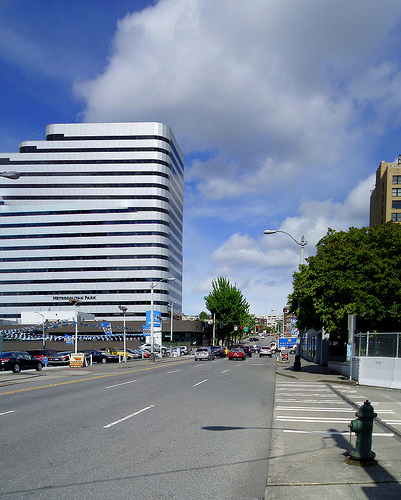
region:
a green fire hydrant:
[339, 394, 395, 463]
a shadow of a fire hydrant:
[362, 460, 399, 497]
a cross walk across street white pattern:
[277, 375, 399, 436]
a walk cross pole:
[342, 317, 352, 379]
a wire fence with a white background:
[356, 332, 400, 385]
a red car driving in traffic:
[225, 346, 248, 364]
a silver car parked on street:
[192, 343, 210, 360]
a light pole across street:
[148, 276, 158, 360]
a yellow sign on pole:
[69, 346, 87, 366]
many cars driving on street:
[192, 320, 285, 376]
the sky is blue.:
[1, 4, 393, 309]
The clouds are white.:
[78, 4, 399, 284]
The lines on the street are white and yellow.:
[0, 355, 244, 442]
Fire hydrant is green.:
[344, 396, 378, 462]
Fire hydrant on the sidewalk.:
[345, 395, 374, 465]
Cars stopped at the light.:
[190, 321, 283, 363]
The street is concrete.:
[0, 345, 289, 496]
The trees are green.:
[276, 218, 399, 329]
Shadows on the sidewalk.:
[194, 410, 400, 495]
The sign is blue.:
[142, 308, 164, 336]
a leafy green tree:
[198, 268, 262, 333]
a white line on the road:
[100, 398, 158, 430]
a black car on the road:
[0, 344, 49, 376]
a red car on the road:
[224, 342, 248, 359]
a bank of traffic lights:
[252, 321, 261, 333]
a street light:
[261, 225, 279, 237]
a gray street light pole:
[286, 233, 310, 369]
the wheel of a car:
[9, 359, 22, 376]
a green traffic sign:
[242, 323, 251, 332]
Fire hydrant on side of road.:
[330, 371, 373, 475]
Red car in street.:
[232, 342, 250, 391]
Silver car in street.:
[192, 340, 226, 400]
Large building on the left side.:
[74, 261, 192, 307]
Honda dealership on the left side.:
[124, 306, 187, 410]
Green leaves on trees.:
[324, 272, 388, 325]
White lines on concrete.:
[284, 394, 328, 459]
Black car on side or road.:
[5, 340, 41, 392]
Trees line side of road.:
[211, 284, 252, 351]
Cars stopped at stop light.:
[223, 319, 295, 371]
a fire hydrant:
[344, 400, 377, 468]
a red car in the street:
[228, 343, 247, 361]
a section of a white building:
[24, 260, 140, 282]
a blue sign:
[279, 333, 297, 347]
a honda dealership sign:
[146, 309, 164, 352]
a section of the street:
[50, 386, 154, 481]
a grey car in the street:
[193, 346, 210, 360]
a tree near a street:
[203, 281, 234, 341]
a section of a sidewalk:
[287, 391, 327, 475]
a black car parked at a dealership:
[5, 348, 42, 373]